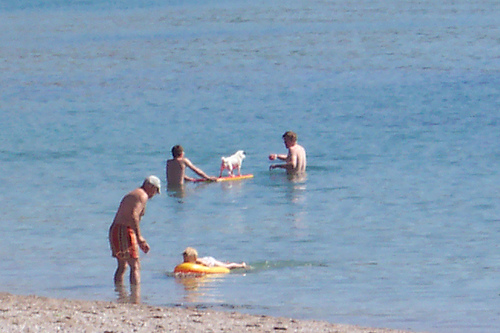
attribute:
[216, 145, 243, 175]
dog — riding, standing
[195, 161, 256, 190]
paddle board — yellow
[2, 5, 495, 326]
water — rippled, blue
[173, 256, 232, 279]
floating device — yellow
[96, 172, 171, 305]
man — standing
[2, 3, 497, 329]
body of water — large, calm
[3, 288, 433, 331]
shore — beach like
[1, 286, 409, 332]
ground — sandy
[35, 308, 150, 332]
sand — brown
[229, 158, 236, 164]
fur — white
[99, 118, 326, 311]
people — swimming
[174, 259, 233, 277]
floaty — yellow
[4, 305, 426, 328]
beach — sandy, tan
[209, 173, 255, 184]
boogie board — orange